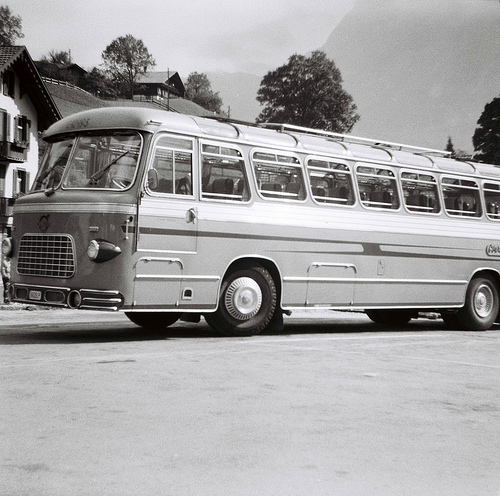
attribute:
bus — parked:
[2, 106, 499, 338]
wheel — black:
[204, 258, 279, 338]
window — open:
[197, 138, 251, 203]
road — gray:
[3, 337, 499, 495]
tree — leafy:
[257, 49, 360, 134]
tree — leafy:
[86, 34, 157, 101]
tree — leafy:
[472, 96, 499, 164]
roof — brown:
[1, 44, 64, 129]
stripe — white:
[12, 191, 499, 242]